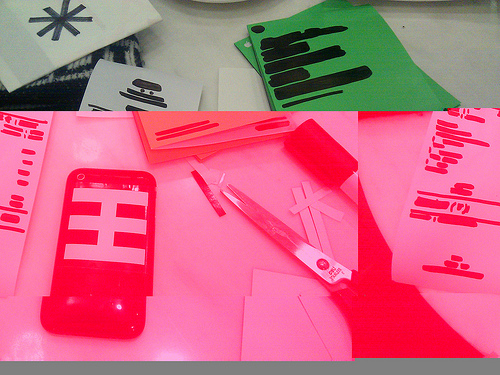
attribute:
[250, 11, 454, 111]
cards — black, green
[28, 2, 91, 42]
star — black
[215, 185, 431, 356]
scissors — pink, metal, red, sharp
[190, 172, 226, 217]
thin — black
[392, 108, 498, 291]
receipt — pink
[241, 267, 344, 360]
paper — white, blank, pink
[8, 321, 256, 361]
table — white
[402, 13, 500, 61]
table — white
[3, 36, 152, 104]
hat — black